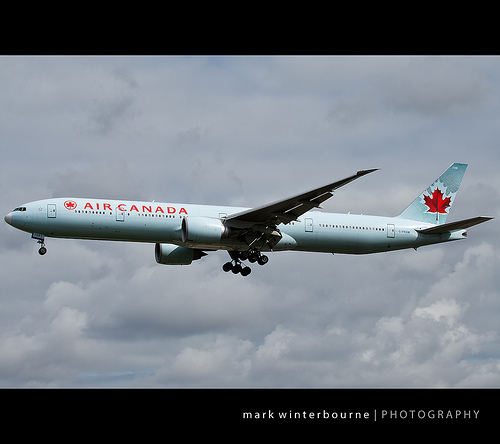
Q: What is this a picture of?
A: A plane.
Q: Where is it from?
A: Canada.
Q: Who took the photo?
A: Mark Winterbourne.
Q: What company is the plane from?
A: Air Canada.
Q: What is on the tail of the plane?
A: A maple leaf.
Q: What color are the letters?
A: Red.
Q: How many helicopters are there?
A: None.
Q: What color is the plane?
A: White and red.